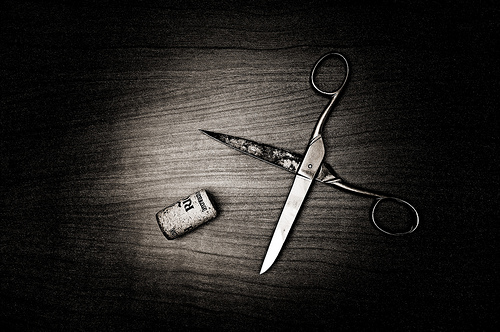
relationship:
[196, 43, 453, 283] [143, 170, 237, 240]
scissors next to cork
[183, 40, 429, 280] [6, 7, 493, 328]
scissors on a wooden surface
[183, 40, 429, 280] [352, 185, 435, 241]
scissors has left handle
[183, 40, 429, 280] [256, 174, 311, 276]
scissors has blade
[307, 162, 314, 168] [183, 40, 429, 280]
screw on scissors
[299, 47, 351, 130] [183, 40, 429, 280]
handle of scissors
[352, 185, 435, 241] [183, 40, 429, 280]
left handle of scissors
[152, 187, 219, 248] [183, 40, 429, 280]
cork next to scissors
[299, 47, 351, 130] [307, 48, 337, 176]
handle on handle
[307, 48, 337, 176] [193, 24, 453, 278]
handle on scissors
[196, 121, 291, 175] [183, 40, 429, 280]
blade on scissors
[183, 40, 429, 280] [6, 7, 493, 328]
scissors on wooden surface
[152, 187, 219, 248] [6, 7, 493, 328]
cork on wooden surface